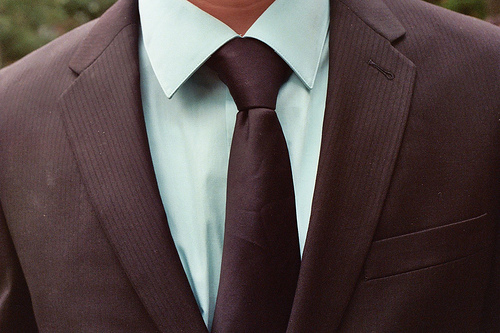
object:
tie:
[208, 39, 300, 333]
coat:
[0, 0, 499, 333]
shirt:
[135, 0, 332, 333]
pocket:
[363, 209, 491, 333]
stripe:
[329, 44, 397, 314]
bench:
[61, 1, 101, 22]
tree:
[2, 14, 48, 54]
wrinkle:
[231, 228, 265, 256]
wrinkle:
[3, 268, 16, 310]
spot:
[43, 170, 57, 188]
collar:
[136, 0, 333, 100]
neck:
[189, 1, 276, 35]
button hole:
[368, 59, 395, 80]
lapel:
[283, 0, 421, 332]